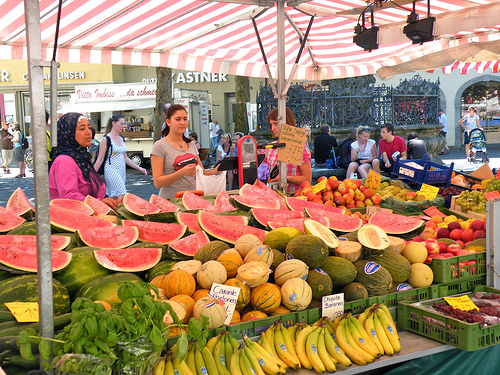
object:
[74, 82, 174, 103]
white sign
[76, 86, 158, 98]
red lettering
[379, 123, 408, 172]
man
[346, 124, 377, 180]
woman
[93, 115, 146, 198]
woman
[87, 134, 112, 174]
backpack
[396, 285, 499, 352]
crate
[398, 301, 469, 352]
edge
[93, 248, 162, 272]
watermelon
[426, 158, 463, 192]
ground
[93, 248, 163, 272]
green watermelon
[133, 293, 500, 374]
table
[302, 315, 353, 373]
yellow bananas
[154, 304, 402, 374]
table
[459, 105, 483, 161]
woman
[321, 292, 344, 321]
sign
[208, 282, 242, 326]
sign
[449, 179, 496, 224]
produce box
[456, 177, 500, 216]
grapes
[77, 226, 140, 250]
water melon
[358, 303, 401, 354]
row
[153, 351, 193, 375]
bananas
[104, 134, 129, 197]
dress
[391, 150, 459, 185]
train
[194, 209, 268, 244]
watermelon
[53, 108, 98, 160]
woman's head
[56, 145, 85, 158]
neck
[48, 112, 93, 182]
wrap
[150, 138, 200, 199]
shirt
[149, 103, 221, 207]
woman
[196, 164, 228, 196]
bag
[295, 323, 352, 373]
bananas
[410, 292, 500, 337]
merchandise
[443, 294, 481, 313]
merchandise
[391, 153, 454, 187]
crate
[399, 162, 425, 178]
fruit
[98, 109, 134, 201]
woman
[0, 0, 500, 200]
town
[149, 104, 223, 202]
consumers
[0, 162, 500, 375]
fruit stand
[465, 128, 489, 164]
stroller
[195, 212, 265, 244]
watermelon slice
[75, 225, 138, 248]
watermelon slice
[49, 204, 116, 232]
watermelon slice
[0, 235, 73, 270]
watermelon slice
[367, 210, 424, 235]
watermelon slice